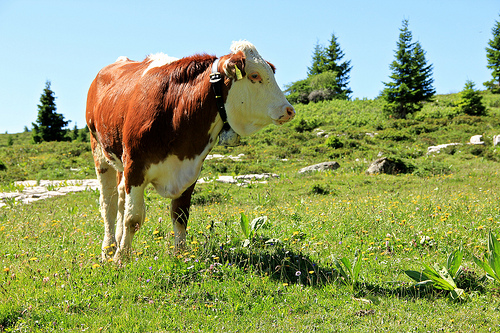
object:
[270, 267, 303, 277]
flower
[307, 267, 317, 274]
flower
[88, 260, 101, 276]
flower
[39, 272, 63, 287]
flower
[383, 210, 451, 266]
flower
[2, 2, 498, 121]
sky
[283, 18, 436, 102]
trees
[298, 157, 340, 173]
rock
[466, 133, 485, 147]
rock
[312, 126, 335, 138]
rock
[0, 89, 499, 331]
hill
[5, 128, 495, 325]
grass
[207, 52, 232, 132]
collar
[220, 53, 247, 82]
ear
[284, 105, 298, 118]
nose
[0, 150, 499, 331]
dandelions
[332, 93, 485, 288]
pasture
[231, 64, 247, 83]
tag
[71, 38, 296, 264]
cow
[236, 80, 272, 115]
face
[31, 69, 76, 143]
tree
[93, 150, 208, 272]
legs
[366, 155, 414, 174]
stone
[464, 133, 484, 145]
stone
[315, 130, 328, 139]
stone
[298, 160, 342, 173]
stone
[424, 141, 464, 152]
stone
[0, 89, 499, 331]
field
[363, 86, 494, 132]
shrubs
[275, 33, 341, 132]
shrubbery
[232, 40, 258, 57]
lump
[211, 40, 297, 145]
head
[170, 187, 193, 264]
leg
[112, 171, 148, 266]
leg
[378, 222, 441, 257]
dandelions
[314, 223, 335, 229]
no objects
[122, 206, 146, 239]
markings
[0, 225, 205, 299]
flowers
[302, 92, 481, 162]
hill